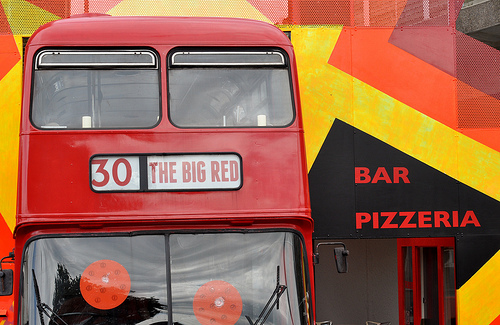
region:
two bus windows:
[28, 42, 296, 136]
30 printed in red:
[91, 150, 143, 192]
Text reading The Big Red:
[148, 156, 241, 185]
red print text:
[148, 159, 240, 188]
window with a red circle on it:
[24, 237, 165, 321]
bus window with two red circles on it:
[22, 233, 302, 323]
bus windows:
[26, 43, 298, 323]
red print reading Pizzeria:
[345, 201, 485, 233]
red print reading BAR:
[350, 159, 480, 196]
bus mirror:
[311, 234, 355, 276]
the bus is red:
[8, 3, 315, 321]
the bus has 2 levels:
[14, 5, 304, 323]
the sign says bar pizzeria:
[339, 149, 492, 244]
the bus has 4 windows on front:
[31, 33, 304, 323]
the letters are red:
[343, 147, 491, 237]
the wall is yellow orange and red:
[1, 1, 471, 321]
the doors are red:
[396, 242, 460, 321]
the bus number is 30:
[78, 126, 170, 210]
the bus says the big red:
[142, 123, 244, 198]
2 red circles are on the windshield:
[59, 257, 252, 323]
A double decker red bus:
[3, 12, 369, 304]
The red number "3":
[84, 148, 113, 197]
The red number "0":
[111, 143, 138, 203]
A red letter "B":
[343, 154, 371, 197]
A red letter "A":
[372, 161, 391, 195]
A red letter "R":
[391, 158, 410, 193]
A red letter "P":
[351, 206, 372, 239]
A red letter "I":
[366, 209, 384, 238]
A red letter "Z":
[378, 204, 398, 243]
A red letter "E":
[417, 208, 433, 236]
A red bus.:
[10, 10, 330, 320]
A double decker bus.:
[16, 20, 328, 322]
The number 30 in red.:
[84, 149, 141, 196]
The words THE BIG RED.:
[144, 152, 241, 188]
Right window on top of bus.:
[27, 36, 157, 131]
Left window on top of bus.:
[165, 35, 295, 140]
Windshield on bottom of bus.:
[22, 231, 314, 321]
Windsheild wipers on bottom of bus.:
[19, 264, 309, 320]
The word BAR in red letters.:
[346, 157, 418, 189]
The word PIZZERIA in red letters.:
[351, 203, 483, 233]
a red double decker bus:
[10, 14, 317, 324]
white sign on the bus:
[88, 151, 241, 193]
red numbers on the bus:
[91, 152, 131, 187]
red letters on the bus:
[148, 154, 240, 186]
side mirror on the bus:
[316, 240, 351, 275]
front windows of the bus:
[21, 46, 308, 323]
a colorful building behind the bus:
[1, 0, 498, 324]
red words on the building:
[354, 164, 481, 227]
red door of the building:
[398, 237, 455, 323]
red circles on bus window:
[78, 259, 243, 324]